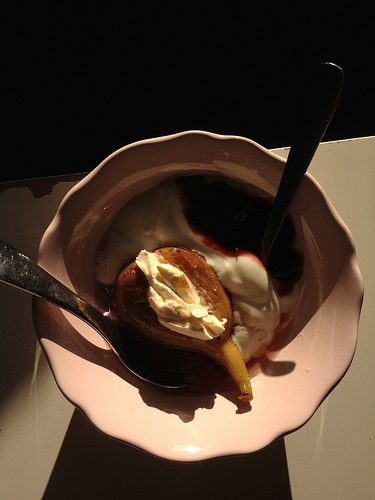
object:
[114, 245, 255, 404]
fig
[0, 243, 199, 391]
spoon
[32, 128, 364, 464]
bowl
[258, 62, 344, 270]
spoon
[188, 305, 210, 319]
food piece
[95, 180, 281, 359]
fruit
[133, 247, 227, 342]
cream